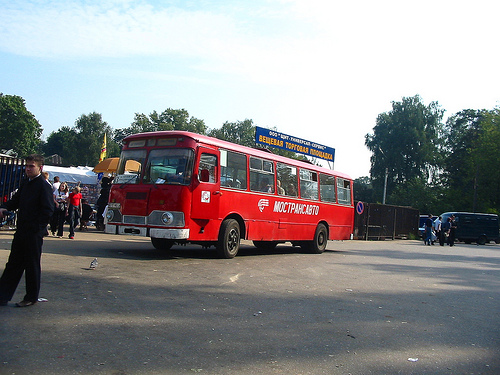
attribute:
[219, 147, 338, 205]
windows — clear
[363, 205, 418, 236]
fence — metal , rusted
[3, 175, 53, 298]
clothing — black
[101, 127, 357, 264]
bus — red 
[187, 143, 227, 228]
door — red, metal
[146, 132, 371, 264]
bus — red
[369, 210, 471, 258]
canopy — light brown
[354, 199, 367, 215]
sign — red and blue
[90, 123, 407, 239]
red bus — large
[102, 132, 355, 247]
bus — red, parked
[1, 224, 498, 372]
pavement — grey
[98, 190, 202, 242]
lights — round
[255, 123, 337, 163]
sign — blue 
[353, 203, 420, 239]
fence — black, metal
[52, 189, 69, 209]
shirt — white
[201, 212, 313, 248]
black tire — large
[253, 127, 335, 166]
blue sign — large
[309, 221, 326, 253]
tire — black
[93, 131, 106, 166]
flag — symbolic, communicative, insightful, honorable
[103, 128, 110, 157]
pole — medium, slim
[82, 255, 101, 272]
bird — small, grey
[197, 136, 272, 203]
window — right window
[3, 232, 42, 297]
pants — black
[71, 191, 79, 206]
shirt — red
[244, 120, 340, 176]
banner — blue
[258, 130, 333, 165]
writing — white, yellow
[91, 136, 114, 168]
flag — yellow